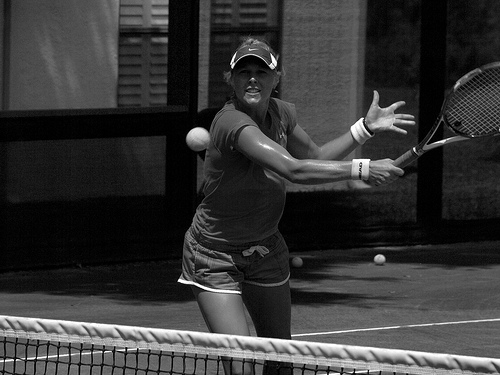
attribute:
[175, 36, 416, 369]
woman — looking, short, playing, holding, wearing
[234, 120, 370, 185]
arm — glistening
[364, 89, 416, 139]
hand — out, open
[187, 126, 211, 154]
ball — flying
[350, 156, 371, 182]
band — absorbent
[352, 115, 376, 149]
band — absorbent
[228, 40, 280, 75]
visor — nike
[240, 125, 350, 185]
sweat — glistening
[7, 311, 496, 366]
line — white